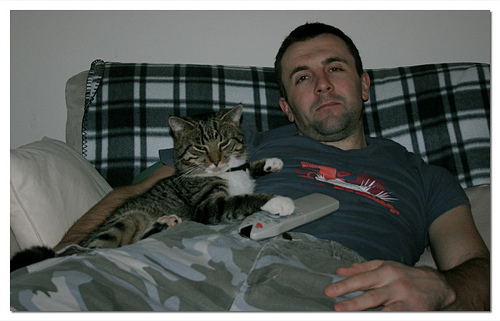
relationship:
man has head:
[9, 22, 491, 312] [273, 22, 371, 138]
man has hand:
[9, 22, 491, 312] [323, 259, 451, 314]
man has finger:
[9, 22, 491, 312] [345, 257, 382, 275]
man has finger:
[9, 22, 491, 312] [324, 271, 381, 300]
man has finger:
[9, 22, 491, 312] [335, 287, 390, 313]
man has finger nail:
[9, 22, 491, 312] [326, 283, 336, 297]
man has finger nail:
[9, 22, 491, 312] [337, 301, 348, 312]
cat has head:
[11, 102, 295, 272] [168, 104, 247, 176]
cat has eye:
[11, 102, 295, 272] [195, 142, 208, 153]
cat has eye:
[11, 102, 295, 272] [220, 138, 231, 148]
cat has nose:
[11, 102, 295, 272] [210, 157, 221, 167]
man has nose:
[9, 22, 491, 312] [314, 72, 335, 96]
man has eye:
[9, 22, 491, 312] [295, 73, 312, 86]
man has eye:
[9, 22, 491, 312] [327, 65, 345, 75]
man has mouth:
[9, 22, 491, 312] [314, 100, 342, 111]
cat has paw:
[11, 102, 295, 272] [193, 192, 295, 226]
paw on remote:
[193, 192, 295, 226] [239, 192, 340, 242]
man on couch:
[9, 22, 491, 312] [10, 63, 491, 268]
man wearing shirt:
[9, 22, 491, 312] [159, 120, 471, 265]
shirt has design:
[159, 120, 471, 265] [294, 159, 400, 216]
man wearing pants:
[9, 22, 491, 312] [9, 220, 382, 312]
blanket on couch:
[82, 57, 492, 189] [10, 63, 491, 268]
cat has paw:
[11, 102, 295, 272] [241, 157, 283, 179]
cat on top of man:
[11, 102, 295, 272] [9, 22, 491, 312]